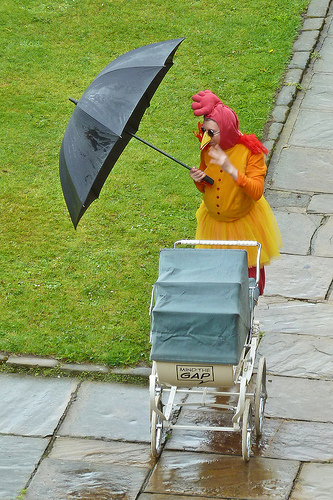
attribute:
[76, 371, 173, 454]
square — stone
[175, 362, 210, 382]
letters — black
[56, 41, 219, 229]
umbrella — open, black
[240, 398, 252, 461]
wheel — small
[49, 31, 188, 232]
umbrella — black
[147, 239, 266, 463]
carriage — cream, blue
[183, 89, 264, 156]
comb — red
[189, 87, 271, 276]
costume — chicken costume